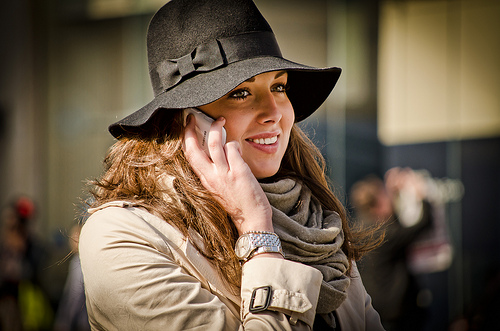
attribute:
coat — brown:
[80, 202, 384, 324]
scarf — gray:
[257, 169, 354, 315]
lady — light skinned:
[76, 39, 386, 329]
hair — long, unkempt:
[80, 83, 390, 298]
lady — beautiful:
[129, 25, 349, 304]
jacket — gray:
[351, 197, 432, 322]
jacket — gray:
[46, 252, 92, 327]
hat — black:
[131, 3, 369, 130]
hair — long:
[128, 130, 226, 257]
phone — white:
[183, 110, 233, 146]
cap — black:
[90, 0, 338, 151]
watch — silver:
[235, 227, 283, 259]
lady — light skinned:
[78, 2, 372, 328]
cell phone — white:
[182, 104, 224, 148]